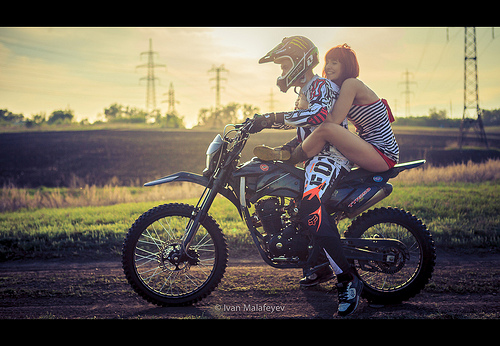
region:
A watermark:
[211, 299, 293, 318]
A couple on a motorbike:
[119, 31, 444, 301]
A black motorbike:
[125, 127, 435, 296]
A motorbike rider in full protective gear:
[238, 35, 345, 310]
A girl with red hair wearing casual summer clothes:
[279, 48, 404, 175]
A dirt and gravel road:
[6, 249, 499, 314]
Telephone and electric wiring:
[6, 25, 291, 120]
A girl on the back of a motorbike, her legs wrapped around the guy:
[259, 50, 404, 177]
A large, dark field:
[4, 115, 491, 180]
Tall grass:
[3, 185, 244, 246]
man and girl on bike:
[129, 37, 421, 321]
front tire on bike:
[123, 191, 231, 296]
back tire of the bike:
[350, 194, 443, 289]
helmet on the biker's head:
[251, 33, 327, 98]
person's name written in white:
[199, 292, 289, 333]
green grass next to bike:
[59, 191, 117, 253]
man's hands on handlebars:
[218, 104, 276, 151]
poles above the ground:
[115, 46, 237, 103]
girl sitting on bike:
[334, 41, 414, 173]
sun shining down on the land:
[206, 30, 264, 59]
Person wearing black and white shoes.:
[318, 262, 361, 324]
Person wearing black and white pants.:
[314, 229, 344, 299]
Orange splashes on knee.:
[295, 182, 332, 251]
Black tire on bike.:
[141, 219, 235, 344]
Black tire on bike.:
[336, 257, 397, 334]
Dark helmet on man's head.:
[265, 45, 344, 156]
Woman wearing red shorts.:
[343, 152, 408, 179]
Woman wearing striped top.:
[358, 107, 409, 182]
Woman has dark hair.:
[324, 50, 380, 141]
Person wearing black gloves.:
[238, 104, 285, 188]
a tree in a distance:
[103, 101, 120, 122]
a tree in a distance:
[48, 102, 77, 124]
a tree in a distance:
[132, 106, 151, 123]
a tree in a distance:
[169, 109, 184, 129]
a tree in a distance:
[221, 99, 241, 128]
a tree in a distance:
[235, 100, 258, 122]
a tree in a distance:
[0, 105, 21, 128]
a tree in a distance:
[21, 108, 41, 128]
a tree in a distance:
[481, 102, 493, 117]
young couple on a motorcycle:
[114, 33, 464, 322]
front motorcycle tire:
[109, 195, 233, 311]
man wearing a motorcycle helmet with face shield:
[248, 33, 325, 95]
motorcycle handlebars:
[225, 102, 285, 143]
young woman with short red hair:
[314, 37, 369, 101]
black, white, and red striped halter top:
[351, 76, 407, 178]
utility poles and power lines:
[130, 37, 167, 119]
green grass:
[7, 197, 122, 260]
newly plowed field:
[4, 133, 159, 174]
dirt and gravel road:
[10, 262, 118, 312]